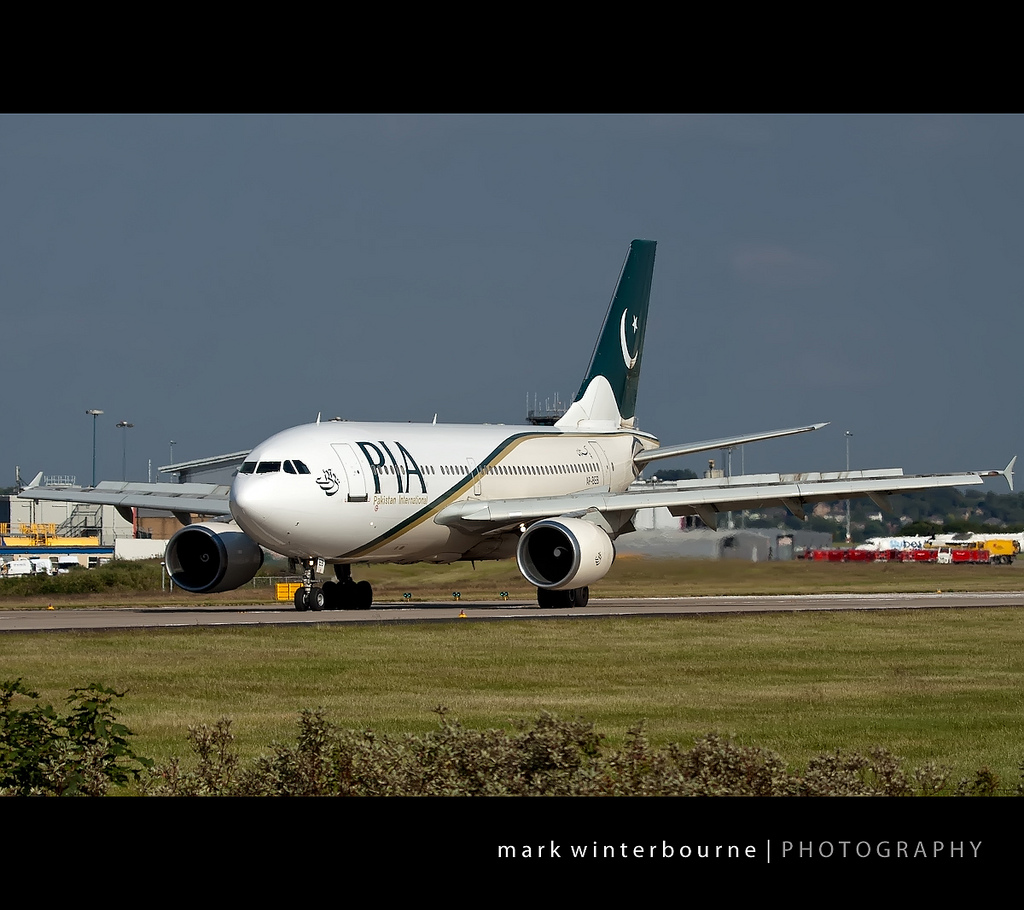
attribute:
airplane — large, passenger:
[144, 420, 698, 602]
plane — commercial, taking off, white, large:
[98, 300, 877, 638]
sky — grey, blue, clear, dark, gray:
[39, 141, 1015, 393]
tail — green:
[598, 234, 659, 421]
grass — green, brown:
[151, 632, 974, 772]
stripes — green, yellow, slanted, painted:
[454, 418, 581, 497]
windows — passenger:
[425, 454, 623, 484]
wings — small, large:
[462, 429, 990, 521]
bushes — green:
[27, 700, 795, 801]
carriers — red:
[835, 540, 951, 562]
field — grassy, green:
[449, 545, 1004, 601]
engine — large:
[505, 514, 611, 599]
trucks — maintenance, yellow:
[777, 30, 1022, 562]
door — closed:
[330, 437, 379, 509]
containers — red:
[816, 542, 908, 556]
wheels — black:
[292, 593, 334, 613]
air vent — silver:
[721, 470, 888, 484]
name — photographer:
[496, 839, 754, 879]